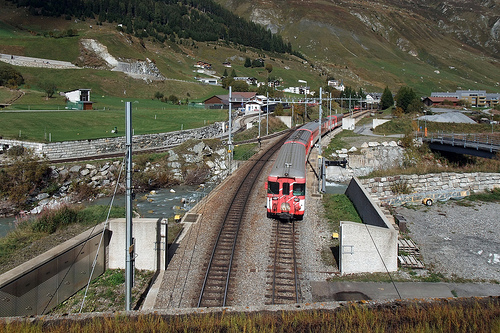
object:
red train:
[266, 114, 345, 220]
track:
[272, 220, 279, 305]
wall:
[327, 137, 425, 183]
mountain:
[0, 0, 500, 111]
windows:
[283, 183, 289, 196]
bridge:
[0, 294, 500, 333]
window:
[293, 183, 305, 196]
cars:
[313, 116, 336, 133]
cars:
[297, 121, 325, 147]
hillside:
[0, 28, 500, 111]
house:
[203, 94, 247, 110]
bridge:
[426, 137, 499, 161]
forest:
[0, 0, 293, 55]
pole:
[126, 101, 133, 313]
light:
[272, 197, 277, 200]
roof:
[268, 143, 305, 179]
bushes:
[0, 160, 52, 207]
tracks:
[267, 220, 302, 302]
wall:
[340, 176, 399, 273]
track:
[292, 220, 299, 303]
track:
[193, 123, 307, 307]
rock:
[170, 188, 176, 192]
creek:
[325, 184, 349, 194]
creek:
[0, 183, 193, 238]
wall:
[359, 171, 500, 207]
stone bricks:
[437, 182, 445, 186]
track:
[222, 143, 283, 306]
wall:
[0, 122, 224, 159]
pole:
[319, 85, 321, 148]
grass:
[0, 296, 499, 332]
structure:
[64, 88, 92, 104]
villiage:
[193, 61, 500, 109]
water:
[157, 191, 169, 201]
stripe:
[286, 196, 295, 203]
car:
[265, 143, 306, 220]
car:
[284, 130, 311, 163]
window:
[267, 181, 279, 194]